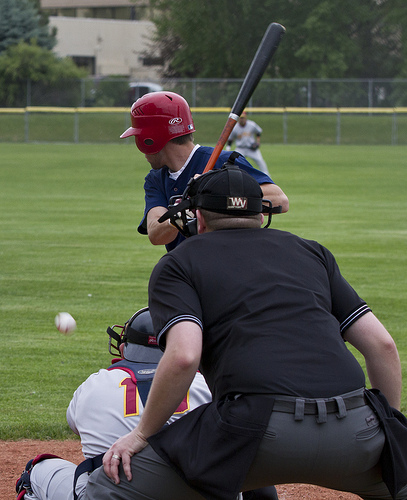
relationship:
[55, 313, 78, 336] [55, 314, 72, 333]
baseball has stitching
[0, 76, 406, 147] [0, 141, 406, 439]
fence around grass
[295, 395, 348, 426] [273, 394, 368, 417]
loops for belt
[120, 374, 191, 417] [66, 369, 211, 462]
number on jersey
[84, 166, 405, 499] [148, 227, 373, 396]
umpire wearing shirt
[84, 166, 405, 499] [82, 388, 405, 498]
umpire wearing pants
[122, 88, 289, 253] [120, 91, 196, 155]
man wearing helmet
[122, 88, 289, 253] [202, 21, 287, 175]
man holding bat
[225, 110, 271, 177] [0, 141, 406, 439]
player in grass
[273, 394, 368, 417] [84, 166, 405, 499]
belt of umpire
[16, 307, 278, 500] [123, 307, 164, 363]
catcher wearing helmet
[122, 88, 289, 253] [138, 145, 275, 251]
man wearing top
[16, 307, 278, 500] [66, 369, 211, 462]
catcher wearing jersey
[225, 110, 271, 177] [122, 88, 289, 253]
player behind man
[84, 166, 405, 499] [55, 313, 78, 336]
umpire watching baseball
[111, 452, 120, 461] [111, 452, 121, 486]
ring on finger